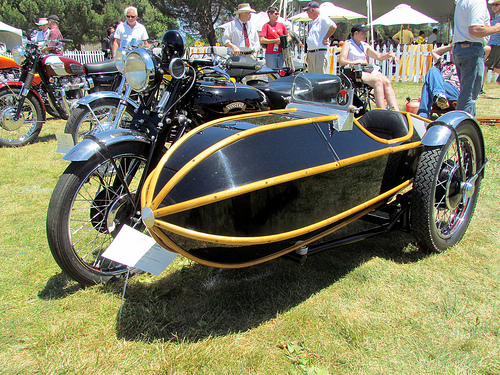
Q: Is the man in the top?
A: Yes, the man is in the top of the image.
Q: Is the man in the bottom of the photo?
A: No, the man is in the top of the image.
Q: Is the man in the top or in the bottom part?
A: The man is in the top of the image.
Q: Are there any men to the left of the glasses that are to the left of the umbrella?
A: Yes, there is a man to the left of the glasses.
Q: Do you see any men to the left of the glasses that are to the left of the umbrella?
A: Yes, there is a man to the left of the glasses.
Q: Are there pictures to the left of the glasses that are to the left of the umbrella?
A: No, there is a man to the left of the glasses.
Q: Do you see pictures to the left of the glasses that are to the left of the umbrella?
A: No, there is a man to the left of the glasses.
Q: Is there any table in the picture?
A: Yes, there is a table.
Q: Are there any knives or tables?
A: Yes, there is a table.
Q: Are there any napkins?
A: No, there are no napkins.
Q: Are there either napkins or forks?
A: No, there are no napkins or forks.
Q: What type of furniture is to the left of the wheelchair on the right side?
A: The piece of furniture is a table.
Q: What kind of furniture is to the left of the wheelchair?
A: The piece of furniture is a table.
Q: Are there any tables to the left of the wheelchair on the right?
A: Yes, there is a table to the left of the wheelchair.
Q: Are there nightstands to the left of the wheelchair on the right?
A: No, there is a table to the left of the wheelchair.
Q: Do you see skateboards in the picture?
A: No, there are no skateboards.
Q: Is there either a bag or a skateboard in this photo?
A: No, there are no skateboards or bags.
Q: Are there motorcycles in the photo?
A: Yes, there is a motorcycle.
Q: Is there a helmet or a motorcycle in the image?
A: Yes, there is a motorcycle.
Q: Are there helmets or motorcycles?
A: Yes, there is a motorcycle.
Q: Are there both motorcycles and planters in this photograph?
A: No, there is a motorcycle but no planters.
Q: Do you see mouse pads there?
A: No, there are no mouse pads.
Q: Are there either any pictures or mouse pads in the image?
A: No, there are no mouse pads or pictures.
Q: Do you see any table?
A: Yes, there is a table.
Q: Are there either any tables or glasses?
A: Yes, there is a table.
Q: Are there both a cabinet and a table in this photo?
A: No, there is a table but no cabinets.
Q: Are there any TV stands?
A: No, there are no TV stands.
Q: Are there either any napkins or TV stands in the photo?
A: No, there are no TV stands or napkins.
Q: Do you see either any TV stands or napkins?
A: No, there are no TV stands or napkins.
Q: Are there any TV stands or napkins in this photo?
A: No, there are no TV stands or napkins.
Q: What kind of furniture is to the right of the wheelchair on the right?
A: The piece of furniture is a table.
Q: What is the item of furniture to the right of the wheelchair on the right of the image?
A: The piece of furniture is a table.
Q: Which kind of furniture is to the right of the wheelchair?
A: The piece of furniture is a table.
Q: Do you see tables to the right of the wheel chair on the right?
A: Yes, there is a table to the right of the wheelchair.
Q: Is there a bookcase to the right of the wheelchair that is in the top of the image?
A: No, there is a table to the right of the wheelchair.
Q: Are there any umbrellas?
A: Yes, there is an umbrella.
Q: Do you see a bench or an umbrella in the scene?
A: Yes, there is an umbrella.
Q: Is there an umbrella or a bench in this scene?
A: Yes, there is an umbrella.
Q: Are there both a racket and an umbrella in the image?
A: No, there is an umbrella but no rackets.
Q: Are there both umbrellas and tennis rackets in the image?
A: No, there is an umbrella but no rackets.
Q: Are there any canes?
A: No, there are no canes.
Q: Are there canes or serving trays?
A: No, there are no canes or serving trays.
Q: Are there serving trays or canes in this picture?
A: No, there are no canes or serving trays.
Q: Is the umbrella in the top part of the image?
A: Yes, the umbrella is in the top of the image.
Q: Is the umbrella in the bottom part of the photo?
A: No, the umbrella is in the top of the image.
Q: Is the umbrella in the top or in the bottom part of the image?
A: The umbrella is in the top of the image.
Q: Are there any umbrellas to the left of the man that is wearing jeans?
A: Yes, there is an umbrella to the left of the man.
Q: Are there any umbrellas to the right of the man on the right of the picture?
A: No, the umbrella is to the left of the man.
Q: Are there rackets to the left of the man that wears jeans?
A: No, there is an umbrella to the left of the man.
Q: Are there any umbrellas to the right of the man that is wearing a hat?
A: Yes, there is an umbrella to the right of the man.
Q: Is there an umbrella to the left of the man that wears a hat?
A: No, the umbrella is to the right of the man.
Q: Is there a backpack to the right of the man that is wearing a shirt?
A: No, there is an umbrella to the right of the man.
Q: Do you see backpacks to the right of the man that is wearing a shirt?
A: No, there is an umbrella to the right of the man.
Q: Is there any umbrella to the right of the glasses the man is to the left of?
A: Yes, there is an umbrella to the right of the glasses.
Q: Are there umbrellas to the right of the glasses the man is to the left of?
A: Yes, there is an umbrella to the right of the glasses.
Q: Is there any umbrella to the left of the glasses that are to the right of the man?
A: No, the umbrella is to the right of the glasses.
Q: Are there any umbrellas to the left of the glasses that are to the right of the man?
A: No, the umbrella is to the right of the glasses.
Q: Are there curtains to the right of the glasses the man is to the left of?
A: No, there is an umbrella to the right of the glasses.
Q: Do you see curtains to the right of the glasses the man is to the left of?
A: No, there is an umbrella to the right of the glasses.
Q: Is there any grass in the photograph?
A: Yes, there is grass.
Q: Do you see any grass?
A: Yes, there is grass.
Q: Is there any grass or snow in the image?
A: Yes, there is grass.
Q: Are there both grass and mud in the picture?
A: No, there is grass but no mud.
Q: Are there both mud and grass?
A: No, there is grass but no mud.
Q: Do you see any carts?
A: No, there are no carts.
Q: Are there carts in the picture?
A: No, there are no carts.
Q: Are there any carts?
A: No, there are no carts.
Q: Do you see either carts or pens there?
A: No, there are no carts or pens.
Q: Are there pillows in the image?
A: No, there are no pillows.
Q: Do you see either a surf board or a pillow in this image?
A: No, there are no pillows or surfboards.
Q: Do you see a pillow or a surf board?
A: No, there are no pillows or surfboards.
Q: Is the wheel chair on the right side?
A: Yes, the wheel chair is on the right of the image.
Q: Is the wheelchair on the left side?
A: No, the wheelchair is on the right of the image.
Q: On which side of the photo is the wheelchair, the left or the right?
A: The wheelchair is on the right of the image.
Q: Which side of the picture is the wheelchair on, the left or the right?
A: The wheelchair is on the right of the image.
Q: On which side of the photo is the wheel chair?
A: The wheel chair is on the right of the image.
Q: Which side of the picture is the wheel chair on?
A: The wheel chair is on the right of the image.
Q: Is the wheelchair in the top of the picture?
A: Yes, the wheelchair is in the top of the image.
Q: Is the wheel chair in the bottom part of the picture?
A: No, the wheel chair is in the top of the image.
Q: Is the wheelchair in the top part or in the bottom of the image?
A: The wheelchair is in the top of the image.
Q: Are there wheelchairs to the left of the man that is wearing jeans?
A: Yes, there is a wheelchair to the left of the man.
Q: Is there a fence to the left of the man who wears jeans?
A: No, there is a wheelchair to the left of the man.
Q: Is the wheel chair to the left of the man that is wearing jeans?
A: Yes, the wheel chair is to the left of the man.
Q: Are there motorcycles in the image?
A: Yes, there is a motorcycle.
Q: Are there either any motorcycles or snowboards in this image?
A: Yes, there is a motorcycle.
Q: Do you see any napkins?
A: No, there are no napkins.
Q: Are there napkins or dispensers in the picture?
A: No, there are no napkins or dispensers.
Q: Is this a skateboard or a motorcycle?
A: This is a motorcycle.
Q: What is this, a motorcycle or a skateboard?
A: This is a motorcycle.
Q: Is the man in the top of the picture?
A: Yes, the man is in the top of the image.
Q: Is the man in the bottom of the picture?
A: No, the man is in the top of the image.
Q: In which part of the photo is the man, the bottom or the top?
A: The man is in the top of the image.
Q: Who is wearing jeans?
A: The man is wearing jeans.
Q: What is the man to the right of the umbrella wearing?
A: The man is wearing jeans.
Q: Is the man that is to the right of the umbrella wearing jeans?
A: Yes, the man is wearing jeans.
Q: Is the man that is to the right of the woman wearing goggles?
A: No, the man is wearing jeans.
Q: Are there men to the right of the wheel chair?
A: Yes, there is a man to the right of the wheel chair.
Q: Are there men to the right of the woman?
A: Yes, there is a man to the right of the woman.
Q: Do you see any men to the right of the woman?
A: Yes, there is a man to the right of the woman.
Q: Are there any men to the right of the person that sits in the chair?
A: Yes, there is a man to the right of the woman.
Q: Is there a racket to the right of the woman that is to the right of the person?
A: No, there is a man to the right of the woman.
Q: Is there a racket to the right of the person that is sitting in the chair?
A: No, there is a man to the right of the woman.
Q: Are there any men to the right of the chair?
A: Yes, there is a man to the right of the chair.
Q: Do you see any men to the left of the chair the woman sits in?
A: No, the man is to the right of the chair.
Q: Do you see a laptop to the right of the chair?
A: No, there is a man to the right of the chair.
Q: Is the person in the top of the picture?
A: Yes, the person is in the top of the image.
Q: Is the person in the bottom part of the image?
A: No, the person is in the top of the image.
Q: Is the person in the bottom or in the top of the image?
A: The person is in the top of the image.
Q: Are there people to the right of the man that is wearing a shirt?
A: Yes, there is a person to the right of the man.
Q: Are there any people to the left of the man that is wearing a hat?
A: No, the person is to the right of the man.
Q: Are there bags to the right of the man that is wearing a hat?
A: No, there is a person to the right of the man.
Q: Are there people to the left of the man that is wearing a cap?
A: Yes, there is a person to the left of the man.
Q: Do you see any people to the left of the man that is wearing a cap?
A: Yes, there is a person to the left of the man.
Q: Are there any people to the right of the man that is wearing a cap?
A: No, the person is to the left of the man.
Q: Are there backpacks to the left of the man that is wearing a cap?
A: No, there is a person to the left of the man.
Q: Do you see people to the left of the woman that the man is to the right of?
A: Yes, there is a person to the left of the woman.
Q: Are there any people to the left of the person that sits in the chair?
A: Yes, there is a person to the left of the woman.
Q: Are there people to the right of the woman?
A: No, the person is to the left of the woman.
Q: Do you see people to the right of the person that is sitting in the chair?
A: No, the person is to the left of the woman.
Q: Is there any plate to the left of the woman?
A: No, there is a person to the left of the woman.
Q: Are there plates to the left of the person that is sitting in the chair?
A: No, there is a person to the left of the woman.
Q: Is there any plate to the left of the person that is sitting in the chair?
A: No, there is a person to the left of the woman.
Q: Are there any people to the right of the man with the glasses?
A: Yes, there is a person to the right of the man.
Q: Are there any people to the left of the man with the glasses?
A: No, the person is to the right of the man.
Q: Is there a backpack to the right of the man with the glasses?
A: No, there is a person to the right of the man.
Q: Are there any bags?
A: No, there are no bags.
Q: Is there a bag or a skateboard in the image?
A: No, there are no bags or skateboards.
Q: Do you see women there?
A: Yes, there is a woman.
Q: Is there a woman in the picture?
A: Yes, there is a woman.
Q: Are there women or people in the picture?
A: Yes, there is a woman.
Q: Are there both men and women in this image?
A: Yes, there are both a woman and a man.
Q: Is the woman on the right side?
A: Yes, the woman is on the right of the image.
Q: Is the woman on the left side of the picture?
A: No, the woman is on the right of the image.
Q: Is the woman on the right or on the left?
A: The woman is on the right of the image.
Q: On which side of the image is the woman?
A: The woman is on the right of the image.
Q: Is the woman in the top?
A: Yes, the woman is in the top of the image.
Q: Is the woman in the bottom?
A: No, the woman is in the top of the image.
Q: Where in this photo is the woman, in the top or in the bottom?
A: The woman is in the top of the image.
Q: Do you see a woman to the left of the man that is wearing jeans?
A: Yes, there is a woman to the left of the man.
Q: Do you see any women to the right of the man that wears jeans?
A: No, the woman is to the left of the man.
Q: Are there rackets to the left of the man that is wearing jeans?
A: No, there is a woman to the left of the man.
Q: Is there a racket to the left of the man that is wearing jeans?
A: No, there is a woman to the left of the man.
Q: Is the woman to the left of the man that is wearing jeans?
A: Yes, the woman is to the left of the man.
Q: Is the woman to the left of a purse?
A: No, the woman is to the left of the man.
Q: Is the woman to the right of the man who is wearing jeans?
A: No, the woman is to the left of the man.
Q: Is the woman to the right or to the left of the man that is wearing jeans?
A: The woman is to the left of the man.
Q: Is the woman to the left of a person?
A: No, the woman is to the right of a person.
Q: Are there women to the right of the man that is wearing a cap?
A: Yes, there is a woman to the right of the man.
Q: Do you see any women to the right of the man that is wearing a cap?
A: Yes, there is a woman to the right of the man.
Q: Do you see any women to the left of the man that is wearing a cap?
A: No, the woman is to the right of the man.